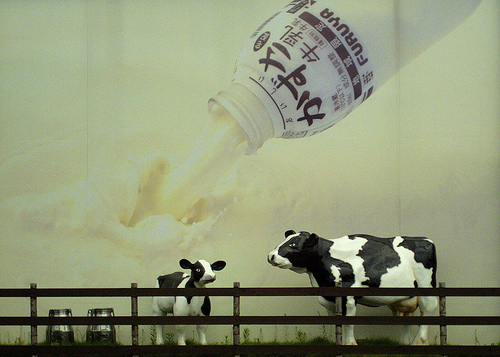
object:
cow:
[267, 229, 436, 345]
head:
[268, 229, 319, 274]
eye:
[288, 243, 295, 247]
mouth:
[273, 264, 290, 268]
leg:
[341, 295, 357, 345]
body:
[266, 229, 440, 346]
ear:
[303, 233, 319, 248]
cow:
[150, 258, 226, 345]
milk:
[15, 151, 231, 254]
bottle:
[203, 0, 484, 153]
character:
[259, 42, 325, 126]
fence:
[0, 280, 500, 355]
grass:
[0, 322, 480, 345]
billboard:
[0, 1, 496, 356]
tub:
[85, 308, 116, 347]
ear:
[179, 259, 194, 270]